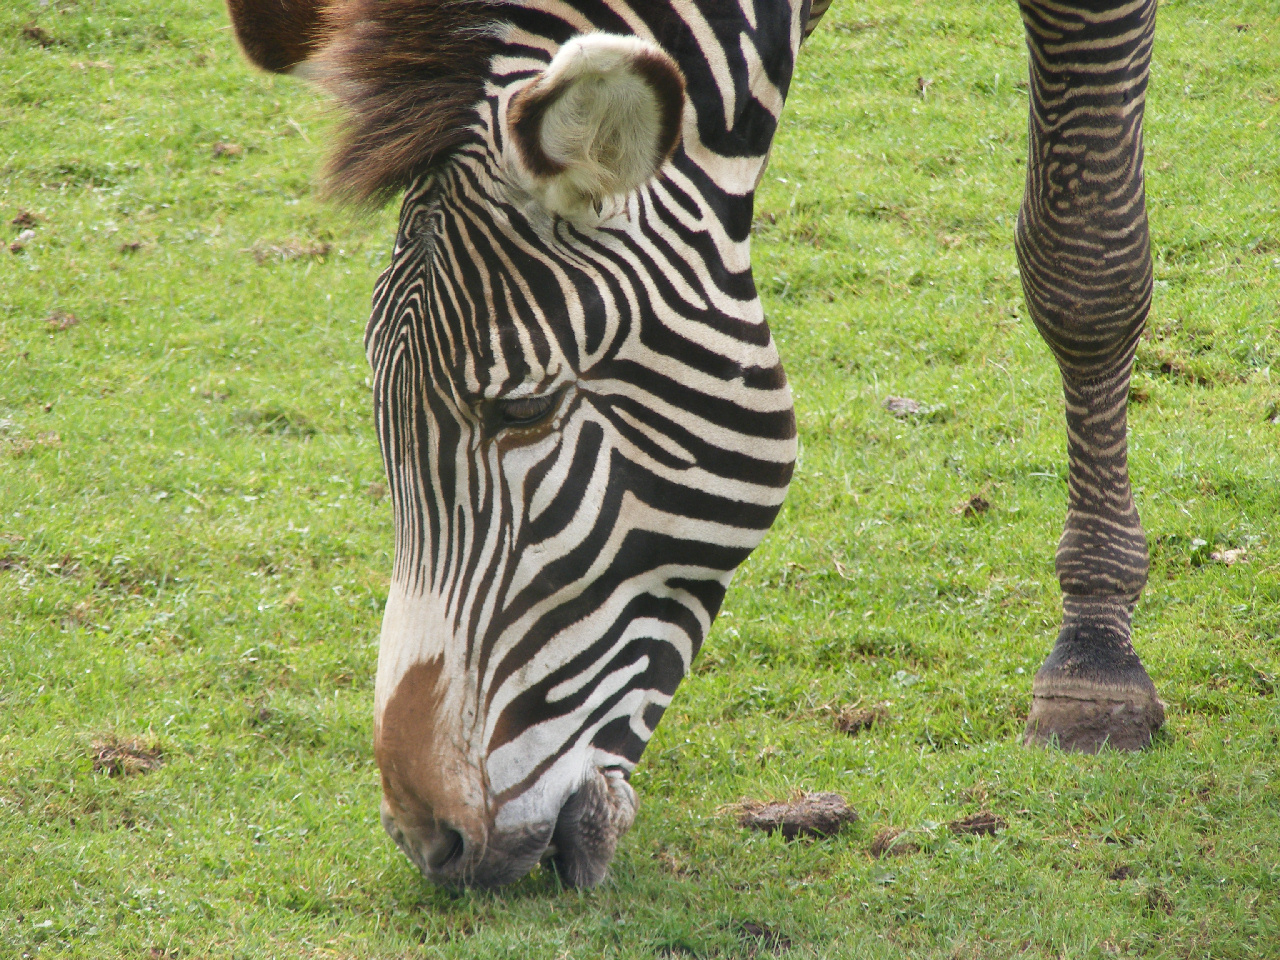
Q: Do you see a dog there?
A: No, there are no dogs.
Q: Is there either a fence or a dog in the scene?
A: No, there are no dogs or fences.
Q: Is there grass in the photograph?
A: Yes, there is grass.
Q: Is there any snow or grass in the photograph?
A: Yes, there is grass.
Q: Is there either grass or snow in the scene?
A: Yes, there is grass.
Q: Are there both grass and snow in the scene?
A: No, there is grass but no snow.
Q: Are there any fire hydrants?
A: No, there are no fire hydrants.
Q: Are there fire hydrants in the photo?
A: No, there are no fire hydrants.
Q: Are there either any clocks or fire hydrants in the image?
A: No, there are no fire hydrants or clocks.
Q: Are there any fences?
A: No, there are no fences.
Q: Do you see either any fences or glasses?
A: No, there are no fences or glasses.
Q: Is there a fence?
A: No, there are no fences.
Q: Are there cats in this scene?
A: No, there are no cats.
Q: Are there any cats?
A: No, there are no cats.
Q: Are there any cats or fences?
A: No, there are no cats or fences.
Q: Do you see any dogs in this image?
A: No, there are no dogs.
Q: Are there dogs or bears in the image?
A: No, there are no dogs or bears.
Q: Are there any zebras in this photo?
A: Yes, there is a zebra.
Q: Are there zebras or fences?
A: Yes, there is a zebra.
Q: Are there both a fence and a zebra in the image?
A: No, there is a zebra but no fences.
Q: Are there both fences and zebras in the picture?
A: No, there is a zebra but no fences.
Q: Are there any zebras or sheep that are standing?
A: Yes, the zebra is standing.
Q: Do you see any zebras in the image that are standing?
A: Yes, there is a zebra that is standing.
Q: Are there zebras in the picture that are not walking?
A: Yes, there is a zebra that is standing.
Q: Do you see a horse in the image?
A: No, there are no horses.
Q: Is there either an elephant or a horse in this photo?
A: No, there are no horses or elephants.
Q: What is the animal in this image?
A: The animal is a zebra.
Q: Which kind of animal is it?
A: The animal is a zebra.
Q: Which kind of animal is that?
A: This is a zebra.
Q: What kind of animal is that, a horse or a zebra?
A: This is a zebra.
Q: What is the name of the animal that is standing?
A: The animal is a zebra.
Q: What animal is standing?
A: The animal is a zebra.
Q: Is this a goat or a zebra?
A: This is a zebra.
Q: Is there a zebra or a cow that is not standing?
A: No, there is a zebra but it is standing.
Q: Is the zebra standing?
A: Yes, the zebra is standing.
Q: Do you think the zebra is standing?
A: Yes, the zebra is standing.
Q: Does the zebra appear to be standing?
A: Yes, the zebra is standing.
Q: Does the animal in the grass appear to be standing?
A: Yes, the zebra is standing.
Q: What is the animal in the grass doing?
A: The zebra is standing.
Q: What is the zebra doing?
A: The zebra is standing.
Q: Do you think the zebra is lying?
A: No, the zebra is standing.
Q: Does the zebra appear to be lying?
A: No, the zebra is standing.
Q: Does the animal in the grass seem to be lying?
A: No, the zebra is standing.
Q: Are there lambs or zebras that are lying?
A: No, there is a zebra but it is standing.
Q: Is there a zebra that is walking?
A: No, there is a zebra but it is standing.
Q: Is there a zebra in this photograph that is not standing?
A: No, there is a zebra but it is standing.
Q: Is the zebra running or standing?
A: The zebra is standing.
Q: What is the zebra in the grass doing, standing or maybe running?
A: The zebra is standing.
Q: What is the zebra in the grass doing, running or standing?
A: The zebra is standing.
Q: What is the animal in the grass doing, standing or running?
A: The zebra is standing.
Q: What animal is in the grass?
A: The zebra is in the grass.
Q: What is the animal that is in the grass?
A: The animal is a zebra.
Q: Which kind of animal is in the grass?
A: The animal is a zebra.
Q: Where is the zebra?
A: The zebra is in the grass.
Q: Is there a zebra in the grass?
A: Yes, there is a zebra in the grass.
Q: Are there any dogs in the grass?
A: No, there is a zebra in the grass.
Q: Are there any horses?
A: No, there are no horses.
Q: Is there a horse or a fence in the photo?
A: No, there are no horses or fences.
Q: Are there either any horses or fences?
A: No, there are no horses or fences.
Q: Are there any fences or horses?
A: No, there are no horses or fences.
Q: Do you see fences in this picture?
A: No, there are no fences.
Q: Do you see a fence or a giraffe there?
A: No, there are no fences or giraffes.